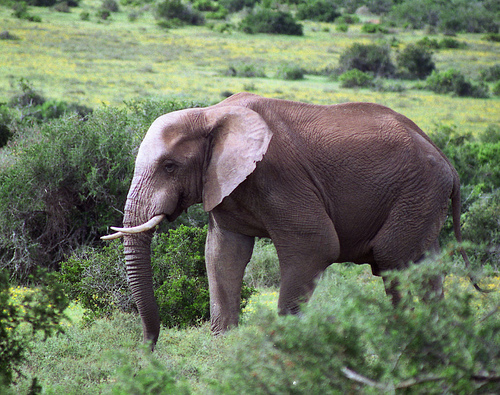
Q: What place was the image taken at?
A: It was taken at the field.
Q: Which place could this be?
A: It is a field.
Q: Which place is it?
A: It is a field.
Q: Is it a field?
A: Yes, it is a field.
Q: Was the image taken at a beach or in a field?
A: It was taken at a field.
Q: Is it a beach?
A: No, it is a field.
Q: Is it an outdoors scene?
A: Yes, it is outdoors.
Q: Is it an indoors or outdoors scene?
A: It is outdoors.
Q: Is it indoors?
A: No, it is outdoors.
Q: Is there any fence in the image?
A: No, there are no fences.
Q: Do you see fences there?
A: No, there are no fences.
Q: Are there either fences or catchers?
A: No, there are no fences or catchers.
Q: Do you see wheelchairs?
A: No, there are no wheelchairs.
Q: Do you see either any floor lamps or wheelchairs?
A: No, there are no wheelchairs or floor lamps.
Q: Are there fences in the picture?
A: No, there are no fences.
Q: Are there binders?
A: No, there are no binders.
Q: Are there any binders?
A: No, there are no binders.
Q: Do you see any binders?
A: No, there are no binders.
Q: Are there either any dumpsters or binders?
A: No, there are no binders or dumpsters.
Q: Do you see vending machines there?
A: No, there are no vending machines.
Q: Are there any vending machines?
A: No, there are no vending machines.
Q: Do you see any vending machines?
A: No, there are no vending machines.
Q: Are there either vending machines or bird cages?
A: No, there are no vending machines or bird cages.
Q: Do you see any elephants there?
A: Yes, there is an elephant.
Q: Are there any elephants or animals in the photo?
A: Yes, there is an elephant.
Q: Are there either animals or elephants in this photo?
A: Yes, there is an elephant.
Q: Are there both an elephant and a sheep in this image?
A: No, there is an elephant but no sheep.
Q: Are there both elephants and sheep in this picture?
A: No, there is an elephant but no sheep.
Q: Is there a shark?
A: No, there are no sharks.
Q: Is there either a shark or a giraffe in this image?
A: No, there are no sharks or giraffes.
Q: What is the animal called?
A: The animal is an elephant.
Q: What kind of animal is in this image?
A: The animal is an elephant.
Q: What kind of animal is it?
A: The animal is an elephant.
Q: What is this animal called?
A: This is an elephant.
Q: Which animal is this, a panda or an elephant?
A: This is an elephant.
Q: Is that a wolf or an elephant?
A: That is an elephant.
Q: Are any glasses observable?
A: No, there are no glasses.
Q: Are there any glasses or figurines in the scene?
A: No, there are no glasses or figurines.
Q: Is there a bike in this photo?
A: No, there are no bikes.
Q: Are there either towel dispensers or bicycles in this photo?
A: No, there are no bicycles or towel dispensers.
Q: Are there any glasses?
A: No, there are no glasses.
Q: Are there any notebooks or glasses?
A: No, there are no glasses or notebooks.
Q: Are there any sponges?
A: No, there are no sponges.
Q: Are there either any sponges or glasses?
A: No, there are no sponges or glasses.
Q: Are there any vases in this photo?
A: No, there are no vases.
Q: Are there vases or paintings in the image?
A: No, there are no vases or paintings.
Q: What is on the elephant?
A: The trunk is on the elephant.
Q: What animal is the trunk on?
A: The trunk is on the elephant.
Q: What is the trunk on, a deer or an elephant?
A: The trunk is on an elephant.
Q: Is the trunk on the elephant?
A: Yes, the trunk is on the elephant.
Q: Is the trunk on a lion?
A: No, the trunk is on the elephant.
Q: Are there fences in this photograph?
A: No, there are no fences.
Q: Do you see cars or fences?
A: No, there are no fences or cars.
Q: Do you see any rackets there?
A: No, there are no rackets.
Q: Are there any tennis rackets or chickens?
A: No, there are no tennis rackets or chickens.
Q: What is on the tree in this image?
A: The leaves are on the tree.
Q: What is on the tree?
A: The leaves are on the tree.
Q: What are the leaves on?
A: The leaves are on the tree.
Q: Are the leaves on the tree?
A: Yes, the leaves are on the tree.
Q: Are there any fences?
A: No, there are no fences.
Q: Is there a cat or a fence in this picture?
A: No, there are no fences or cats.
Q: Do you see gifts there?
A: No, there are no gifts.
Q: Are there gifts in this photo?
A: No, there are no gifts.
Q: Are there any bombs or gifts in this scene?
A: No, there are no gifts or bombs.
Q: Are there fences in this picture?
A: No, there are no fences.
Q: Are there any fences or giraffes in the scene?
A: No, there are no fences or giraffes.